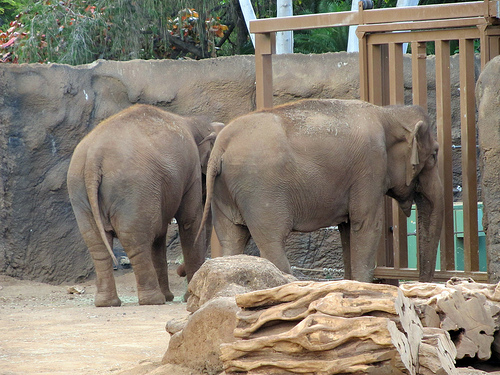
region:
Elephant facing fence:
[215, 98, 440, 275]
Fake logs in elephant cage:
[238, 284, 497, 358]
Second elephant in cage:
[65, 105, 220, 310]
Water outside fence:
[387, 212, 497, 266]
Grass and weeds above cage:
[5, 4, 241, 49]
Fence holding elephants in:
[254, 25, 497, 276]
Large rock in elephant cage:
[182, 259, 300, 308]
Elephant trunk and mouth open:
[389, 110, 452, 278]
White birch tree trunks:
[236, 3, 438, 48]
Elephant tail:
[72, 148, 127, 265]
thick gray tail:
[88, 183, 120, 268]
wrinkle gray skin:
[284, 130, 311, 162]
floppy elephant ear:
[409, 122, 423, 179]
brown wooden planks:
[376, 34, 477, 101]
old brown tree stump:
[236, 292, 419, 367]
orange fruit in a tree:
[172, 7, 222, 42]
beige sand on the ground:
[10, 325, 131, 367]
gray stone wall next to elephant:
[3, 85, 69, 278]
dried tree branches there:
[70, 25, 91, 56]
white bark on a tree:
[277, 29, 294, 51]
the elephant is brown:
[221, 114, 362, 279]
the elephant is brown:
[98, 104, 207, 212]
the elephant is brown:
[306, 76, 446, 225]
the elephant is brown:
[80, 129, 180, 229]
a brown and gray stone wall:
[10, 66, 75, 196]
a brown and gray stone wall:
[18, 154, 85, 272]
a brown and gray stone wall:
[106, 74, 201, 113]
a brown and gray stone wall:
[279, 232, 359, 272]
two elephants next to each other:
[61, 80, 445, 312]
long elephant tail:
[79, 170, 116, 271]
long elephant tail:
[187, 158, 227, 240]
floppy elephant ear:
[404, 125, 418, 182]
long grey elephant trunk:
[409, 183, 451, 281]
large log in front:
[224, 271, 418, 365]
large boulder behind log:
[164, 249, 292, 337]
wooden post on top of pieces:
[245, 0, 487, 37]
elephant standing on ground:
[180, 108, 444, 281]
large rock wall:
[1, 55, 96, 282]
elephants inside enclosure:
[18, 8, 496, 348]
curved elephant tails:
[75, 131, 231, 271]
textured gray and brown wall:
[0, 60, 365, 286]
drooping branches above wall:
[5, 5, 172, 66]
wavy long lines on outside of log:
[225, 276, 390, 371]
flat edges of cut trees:
[391, 292, 492, 369]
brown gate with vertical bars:
[247, 2, 489, 277]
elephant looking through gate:
[380, 100, 480, 280]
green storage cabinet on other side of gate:
[397, 197, 487, 273]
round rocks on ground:
[163, 248, 278, 369]